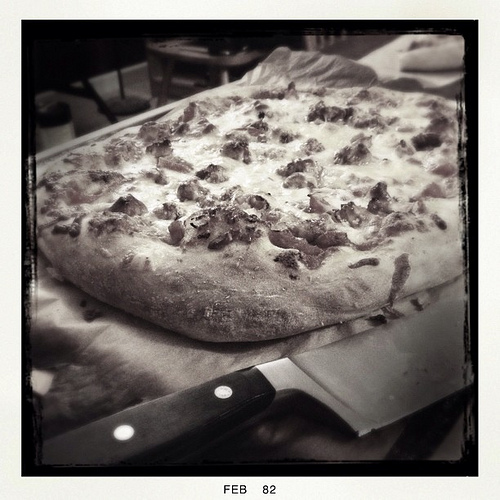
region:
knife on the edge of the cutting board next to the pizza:
[23, 291, 466, 470]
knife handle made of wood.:
[44, 362, 280, 470]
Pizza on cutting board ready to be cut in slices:
[33, 86, 463, 336]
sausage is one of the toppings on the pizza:
[275, 211, 346, 270]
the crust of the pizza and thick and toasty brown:
[31, 58, 464, 340]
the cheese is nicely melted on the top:
[26, 70, 464, 340]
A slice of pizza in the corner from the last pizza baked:
[398, 33, 465, 74]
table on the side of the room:
[148, 38, 258, 123]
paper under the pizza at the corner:
[223, 45, 464, 90]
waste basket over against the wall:
[31, 102, 78, 142]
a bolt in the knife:
[209, 380, 236, 402]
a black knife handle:
[40, 362, 271, 462]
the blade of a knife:
[251, 287, 471, 443]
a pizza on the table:
[25, 78, 462, 343]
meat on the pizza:
[172, 176, 211, 206]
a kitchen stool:
[135, 35, 265, 109]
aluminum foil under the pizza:
[23, 47, 463, 457]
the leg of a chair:
[147, 60, 174, 109]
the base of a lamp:
[90, 90, 154, 117]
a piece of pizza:
[401, 35, 469, 80]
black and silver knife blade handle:
[31, 361, 270, 474]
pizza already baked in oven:
[36, 78, 459, 327]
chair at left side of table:
[306, 33, 349, 45]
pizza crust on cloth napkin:
[101, 242, 274, 343]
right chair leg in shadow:
[148, 41, 180, 101]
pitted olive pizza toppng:
[245, 192, 270, 210]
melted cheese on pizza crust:
[347, 255, 414, 307]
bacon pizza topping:
[268, 226, 322, 261]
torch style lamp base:
[98, 20, 150, 115]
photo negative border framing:
[21, 20, 44, 470]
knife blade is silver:
[309, 332, 451, 436]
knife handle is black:
[104, 377, 288, 452]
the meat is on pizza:
[152, 165, 396, 325]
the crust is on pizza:
[162, 246, 379, 346]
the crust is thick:
[99, 227, 404, 324]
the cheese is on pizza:
[227, 157, 433, 195]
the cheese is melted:
[237, 155, 410, 207]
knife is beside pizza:
[168, 198, 462, 463]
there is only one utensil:
[201, 318, 469, 456]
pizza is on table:
[36, 122, 465, 389]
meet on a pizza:
[180, 194, 253, 256]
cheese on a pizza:
[242, 167, 272, 189]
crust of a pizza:
[178, 265, 249, 330]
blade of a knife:
[379, 395, 446, 432]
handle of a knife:
[177, 378, 267, 443]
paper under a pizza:
[266, 47, 301, 91]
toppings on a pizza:
[136, 115, 218, 170]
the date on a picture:
[219, 476, 282, 498]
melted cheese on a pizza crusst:
[103, 242, 155, 277]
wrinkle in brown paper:
[63, 317, 120, 355]